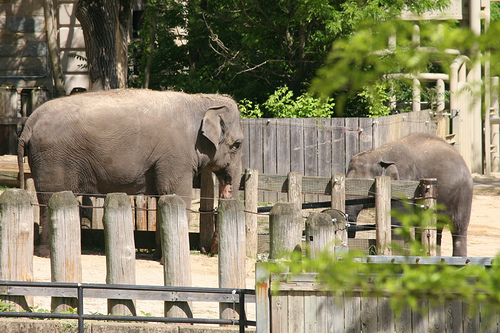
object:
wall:
[0, 0, 188, 124]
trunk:
[205, 157, 240, 256]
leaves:
[483, 301, 500, 320]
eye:
[233, 142, 242, 151]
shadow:
[314, 294, 500, 332]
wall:
[253, 260, 500, 332]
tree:
[68, 0, 452, 119]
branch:
[228, 58, 283, 82]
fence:
[253, 253, 500, 332]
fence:
[0, 168, 438, 332]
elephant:
[16, 86, 243, 260]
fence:
[242, 109, 443, 208]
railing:
[0, 279, 255, 297]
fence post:
[154, 191, 191, 319]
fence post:
[45, 187, 82, 314]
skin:
[89, 114, 137, 164]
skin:
[389, 147, 409, 169]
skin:
[192, 104, 205, 132]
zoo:
[0, 0, 499, 332]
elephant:
[342, 131, 473, 257]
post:
[215, 195, 245, 329]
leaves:
[440, 272, 457, 288]